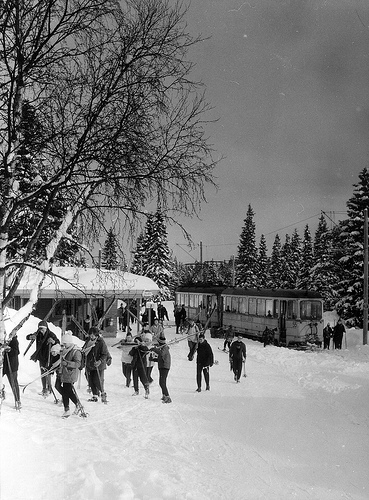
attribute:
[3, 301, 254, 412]
people — walking, lining, standing, carrying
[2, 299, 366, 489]
snow — a lot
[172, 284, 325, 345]
train — black, white, old style, trolley, here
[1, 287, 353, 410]
crowd — black, white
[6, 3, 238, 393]
trees — white, black, covered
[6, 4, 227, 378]
tree — leafless, big, tall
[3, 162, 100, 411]
snow — white, sticking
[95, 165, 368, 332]
snow — white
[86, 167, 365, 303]
trees — pine, big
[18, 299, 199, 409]
equipment — ski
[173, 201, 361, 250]
cables — supported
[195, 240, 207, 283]
pole — electricity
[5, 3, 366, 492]
weather — cold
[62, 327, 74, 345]
hat — white, ski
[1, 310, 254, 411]
group — people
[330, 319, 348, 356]
person — standing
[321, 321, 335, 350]
person — standing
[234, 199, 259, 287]
tree — tall, pine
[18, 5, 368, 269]
sky — clear, gray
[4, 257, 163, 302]
top — building's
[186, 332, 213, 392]
man — walking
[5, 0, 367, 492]
image — black, white, day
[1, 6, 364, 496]
day — snowy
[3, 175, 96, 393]
trunk — tree's